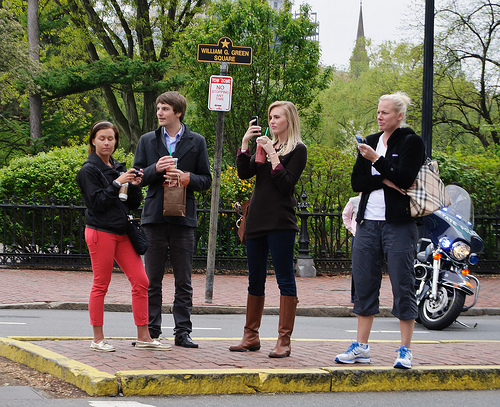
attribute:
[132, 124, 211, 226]
jacket — black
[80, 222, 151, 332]
pants — red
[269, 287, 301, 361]
boot — brown, leather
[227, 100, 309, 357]
woman — picture-taking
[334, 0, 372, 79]
building — pointed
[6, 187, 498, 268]
fence — black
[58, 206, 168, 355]
jeans — red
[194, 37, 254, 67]
sign — William G. Green Square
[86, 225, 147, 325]
jean — red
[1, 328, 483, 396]
meridian — yellow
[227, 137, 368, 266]
bush — green